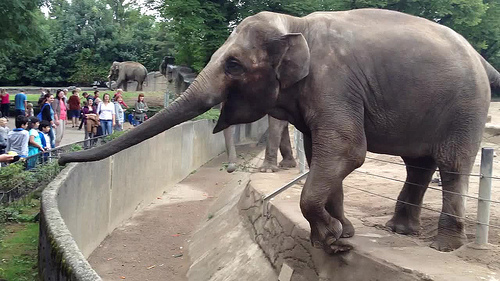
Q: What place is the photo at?
A: It is at the pen.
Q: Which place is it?
A: It is a pen.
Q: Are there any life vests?
A: No, there are no life vests.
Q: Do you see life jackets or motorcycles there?
A: No, there are no life jackets or motorcycles.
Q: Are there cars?
A: No, there are no cars.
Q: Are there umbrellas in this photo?
A: No, there are no umbrellas.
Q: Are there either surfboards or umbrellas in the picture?
A: No, there are no umbrellas or surfboards.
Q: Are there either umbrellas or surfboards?
A: No, there are no umbrellas or surfboards.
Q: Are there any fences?
A: Yes, there is a fence.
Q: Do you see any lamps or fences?
A: Yes, there is a fence.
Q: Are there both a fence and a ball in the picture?
A: No, there is a fence but no balls.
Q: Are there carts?
A: No, there are no carts.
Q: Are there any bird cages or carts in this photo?
A: No, there are no carts or bird cages.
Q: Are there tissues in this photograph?
A: No, there are no tissues.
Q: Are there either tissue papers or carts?
A: No, there are no tissue papers or carts.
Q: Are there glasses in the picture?
A: No, there are no glasses.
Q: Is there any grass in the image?
A: Yes, there is grass.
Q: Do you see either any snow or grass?
A: Yes, there is grass.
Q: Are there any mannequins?
A: No, there are no mannequins.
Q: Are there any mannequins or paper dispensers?
A: No, there are no mannequins or paper dispensers.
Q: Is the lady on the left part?
A: Yes, the lady is on the left of the image.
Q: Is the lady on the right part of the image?
A: No, the lady is on the left of the image.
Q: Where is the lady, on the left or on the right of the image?
A: The lady is on the left of the image.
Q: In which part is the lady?
A: The lady is on the left of the image.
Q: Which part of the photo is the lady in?
A: The lady is on the left of the image.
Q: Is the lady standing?
A: Yes, the lady is standing.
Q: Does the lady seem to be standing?
A: Yes, the lady is standing.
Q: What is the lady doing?
A: The lady is standing.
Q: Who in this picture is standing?
A: The lady is standing.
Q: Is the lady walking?
A: No, the lady is standing.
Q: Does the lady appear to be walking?
A: No, the lady is standing.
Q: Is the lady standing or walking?
A: The lady is standing.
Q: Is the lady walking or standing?
A: The lady is standing.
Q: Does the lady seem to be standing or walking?
A: The lady is standing.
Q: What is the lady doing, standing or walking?
A: The lady is standing.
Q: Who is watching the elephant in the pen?
A: The lady is watching the elephant.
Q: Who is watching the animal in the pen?
A: The lady is watching the elephant.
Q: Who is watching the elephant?
A: The lady is watching the elephant.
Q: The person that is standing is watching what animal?
A: The lady is watching the elephant.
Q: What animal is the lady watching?
A: The lady is watching the elephant.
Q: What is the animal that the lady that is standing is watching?
A: The animal is an elephant.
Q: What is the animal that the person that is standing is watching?
A: The animal is an elephant.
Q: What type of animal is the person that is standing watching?
A: The lady is watching the elephant.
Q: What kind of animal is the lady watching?
A: The lady is watching the elephant.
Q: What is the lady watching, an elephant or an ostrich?
A: The lady is watching an elephant.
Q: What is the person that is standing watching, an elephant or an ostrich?
A: The lady is watching an elephant.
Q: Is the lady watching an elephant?
A: Yes, the lady is watching an elephant.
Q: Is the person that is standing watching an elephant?
A: Yes, the lady is watching an elephant.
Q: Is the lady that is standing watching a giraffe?
A: No, the lady is watching an elephant.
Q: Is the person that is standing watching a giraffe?
A: No, the lady is watching an elephant.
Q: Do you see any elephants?
A: Yes, there is an elephant.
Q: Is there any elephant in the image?
A: Yes, there is an elephant.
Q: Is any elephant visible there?
A: Yes, there is an elephant.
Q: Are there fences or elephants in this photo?
A: Yes, there is an elephant.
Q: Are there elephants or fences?
A: Yes, there is an elephant.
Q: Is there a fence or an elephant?
A: Yes, there is an elephant.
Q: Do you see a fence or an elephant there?
A: Yes, there is an elephant.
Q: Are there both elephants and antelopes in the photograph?
A: No, there is an elephant but no antelopes.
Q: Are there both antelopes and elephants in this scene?
A: No, there is an elephant but no antelopes.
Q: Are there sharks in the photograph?
A: No, there are no sharks.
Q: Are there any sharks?
A: No, there are no sharks.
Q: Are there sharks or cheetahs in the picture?
A: No, there are no sharks or cheetahs.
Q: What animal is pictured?
A: The animal is an elephant.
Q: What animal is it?
A: The animal is an elephant.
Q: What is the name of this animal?
A: This is an elephant.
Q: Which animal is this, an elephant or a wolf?
A: This is an elephant.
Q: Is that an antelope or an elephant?
A: That is an elephant.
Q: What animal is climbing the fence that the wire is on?
A: The elephant is climbing the fence.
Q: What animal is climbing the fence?
A: The elephant is climbing the fence.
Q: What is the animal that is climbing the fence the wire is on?
A: The animal is an elephant.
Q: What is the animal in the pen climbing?
A: The elephant is climbing the fence.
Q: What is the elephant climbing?
A: The elephant is climbing the fence.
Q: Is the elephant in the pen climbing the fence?
A: Yes, the elephant is climbing the fence.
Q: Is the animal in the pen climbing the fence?
A: Yes, the elephant is climbing the fence.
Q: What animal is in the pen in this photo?
A: The elephant is in the pen.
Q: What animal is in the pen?
A: The elephant is in the pen.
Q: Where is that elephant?
A: The elephant is in the pen.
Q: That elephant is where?
A: The elephant is in the pen.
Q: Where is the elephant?
A: The elephant is in the pen.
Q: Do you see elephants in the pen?
A: Yes, there is an elephant in the pen.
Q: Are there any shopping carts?
A: No, there are no shopping carts.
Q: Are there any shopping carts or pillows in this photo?
A: No, there are no shopping carts or pillows.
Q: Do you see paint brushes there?
A: No, there are no paint brushes.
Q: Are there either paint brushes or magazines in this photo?
A: No, there are no paint brushes or magazines.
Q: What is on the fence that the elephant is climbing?
A: The wire is on the fence.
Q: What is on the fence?
A: The wire is on the fence.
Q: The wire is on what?
A: The wire is on the fence.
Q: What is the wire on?
A: The wire is on the fence.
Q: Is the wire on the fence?
A: Yes, the wire is on the fence.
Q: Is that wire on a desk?
A: No, the wire is on the fence.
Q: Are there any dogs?
A: No, there are no dogs.